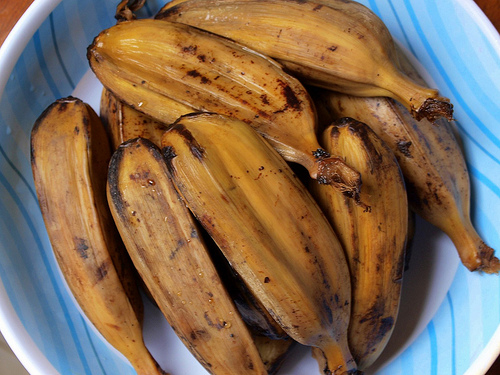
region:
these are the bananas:
[81, 26, 426, 346]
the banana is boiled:
[146, 24, 207, 94]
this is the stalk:
[383, 72, 448, 114]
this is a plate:
[433, 11, 484, 81]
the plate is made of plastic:
[451, 312, 483, 352]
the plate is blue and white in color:
[12, 24, 46, 66]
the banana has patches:
[191, 58, 228, 91]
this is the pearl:
[180, 125, 235, 170]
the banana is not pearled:
[205, 138, 292, 255]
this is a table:
[3, 5, 15, 15]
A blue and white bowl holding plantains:
[0, 0, 496, 371]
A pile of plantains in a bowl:
[31, 1, 495, 368]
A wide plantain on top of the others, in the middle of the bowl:
[156, 110, 356, 372]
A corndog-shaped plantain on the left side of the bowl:
[30, 92, 172, 369]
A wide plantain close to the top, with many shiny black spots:
[87, 13, 357, 189]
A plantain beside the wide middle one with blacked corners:
[100, 136, 267, 372]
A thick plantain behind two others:
[307, 111, 404, 371]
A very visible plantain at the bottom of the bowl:
[320, 66, 496, 279]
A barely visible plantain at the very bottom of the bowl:
[220, 315, 298, 371]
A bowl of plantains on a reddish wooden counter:
[0, 1, 499, 373]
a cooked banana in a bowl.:
[22, 96, 162, 371]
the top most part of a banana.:
[305, 128, 370, 222]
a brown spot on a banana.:
[64, 213, 96, 278]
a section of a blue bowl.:
[433, 21, 486, 70]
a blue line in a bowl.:
[443, 294, 458, 374]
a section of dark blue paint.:
[413, 317, 440, 372]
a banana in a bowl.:
[150, 0, 434, 125]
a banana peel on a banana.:
[179, 118, 293, 291]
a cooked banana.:
[85, 7, 417, 184]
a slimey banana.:
[90, 128, 287, 372]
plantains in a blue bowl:
[1, 0, 493, 370]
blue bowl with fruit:
[0, 1, 486, 371]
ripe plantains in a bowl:
[2, 0, 494, 370]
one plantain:
[22, 90, 137, 362]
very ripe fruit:
[0, 1, 495, 371]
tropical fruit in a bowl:
[3, 1, 496, 369]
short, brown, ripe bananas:
[0, 0, 498, 371]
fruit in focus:
[1, 1, 493, 366]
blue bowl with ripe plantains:
[1, 3, 486, 370]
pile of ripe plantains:
[3, 0, 498, 370]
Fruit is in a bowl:
[30, 1, 499, 373]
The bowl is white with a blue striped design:
[1, 1, 499, 373]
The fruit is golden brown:
[27, 0, 494, 374]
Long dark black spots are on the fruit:
[96, 129, 216, 255]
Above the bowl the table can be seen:
[1, 1, 498, 51]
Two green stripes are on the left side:
[0, 13, 107, 373]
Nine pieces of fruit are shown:
[30, 1, 499, 374]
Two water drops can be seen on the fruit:
[126, 91, 169, 231]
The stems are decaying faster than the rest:
[303, 87, 497, 279]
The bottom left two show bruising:
[79, 256, 239, 365]